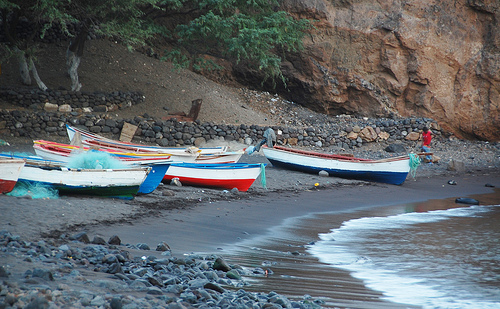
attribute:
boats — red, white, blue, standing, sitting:
[1, 128, 440, 200]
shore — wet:
[114, 178, 499, 262]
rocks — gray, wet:
[57, 234, 228, 308]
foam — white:
[318, 207, 427, 308]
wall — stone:
[4, 105, 444, 150]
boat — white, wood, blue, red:
[263, 140, 413, 185]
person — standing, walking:
[419, 124, 433, 163]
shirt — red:
[420, 129, 437, 146]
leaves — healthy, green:
[226, 20, 262, 42]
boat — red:
[161, 155, 266, 194]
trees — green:
[6, 5, 309, 98]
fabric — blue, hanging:
[260, 162, 267, 189]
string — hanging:
[407, 155, 422, 181]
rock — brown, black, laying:
[69, 230, 92, 246]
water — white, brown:
[353, 236, 447, 263]